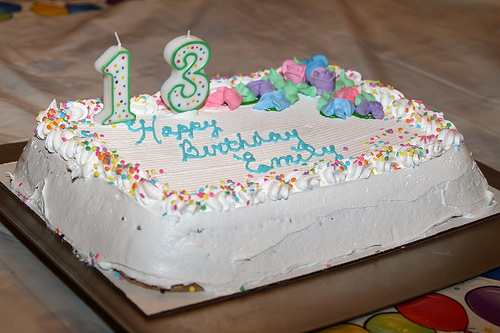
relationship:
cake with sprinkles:
[6, 53, 498, 281] [94, 146, 164, 195]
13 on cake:
[94, 30, 211, 125] [6, 53, 498, 281]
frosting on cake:
[6, 134, 488, 298] [6, 53, 498, 281]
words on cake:
[129, 113, 346, 172] [6, 53, 498, 281]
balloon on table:
[364, 312, 435, 333] [2, 0, 499, 332]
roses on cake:
[208, 53, 382, 120] [6, 53, 498, 281]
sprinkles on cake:
[94, 146, 164, 195] [6, 53, 498, 281]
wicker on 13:
[113, 31, 123, 46] [94, 30, 211, 125]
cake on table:
[6, 53, 498, 281] [2, 0, 499, 332]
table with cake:
[2, 0, 499, 332] [6, 53, 498, 281]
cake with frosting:
[6, 53, 498, 281] [6, 134, 488, 298]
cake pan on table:
[1, 141, 499, 333] [2, 0, 499, 332]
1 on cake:
[95, 30, 137, 125] [6, 53, 498, 281]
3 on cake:
[163, 30, 210, 111] [6, 53, 498, 281]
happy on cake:
[125, 115, 223, 142] [6, 53, 498, 281]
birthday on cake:
[179, 129, 308, 161] [6, 53, 498, 281]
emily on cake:
[232, 144, 343, 175] [6, 53, 498, 281]